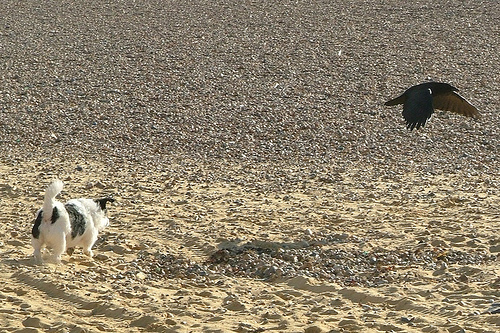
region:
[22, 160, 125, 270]
a white and black dog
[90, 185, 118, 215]
ear of dog is black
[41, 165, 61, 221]
tail of dog is white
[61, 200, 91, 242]
a brown spot on body of dog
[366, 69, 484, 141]
a bird flying in the air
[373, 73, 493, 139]
bird is black and brown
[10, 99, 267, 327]
dog stand in the sand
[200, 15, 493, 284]
bird flying on a field of sand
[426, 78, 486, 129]
wing of bird is brown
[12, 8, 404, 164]
field filled with gravel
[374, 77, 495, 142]
the bird is black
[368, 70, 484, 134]
the bird is flying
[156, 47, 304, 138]
the gravel is gray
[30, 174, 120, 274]
the dog is walking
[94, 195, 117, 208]
the ear is black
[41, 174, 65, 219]
the tail is white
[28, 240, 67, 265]
the dog has back legs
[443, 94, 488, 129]
the bird has a wing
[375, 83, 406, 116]
the bird has a tail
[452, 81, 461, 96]
the bird has a beek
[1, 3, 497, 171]
THE PEBBLES ARE ON THE GROUND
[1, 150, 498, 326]
THE GROUND IS VERY SANDY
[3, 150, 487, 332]
THE SAND HAS MANY TRACKS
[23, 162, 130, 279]
THE DOG IS CHASING THE BIRD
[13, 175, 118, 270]
THE DOG IS BLACK AND WHITE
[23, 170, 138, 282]
THIS IS A DOG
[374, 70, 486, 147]
THIS IS A BIRD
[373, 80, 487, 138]
THE BIRD IS BLACK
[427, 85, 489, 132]
THE UNDERSIDE OF THE BIRD'S WING IS BROWN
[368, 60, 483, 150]
THE BIRD IS FLYING AWAY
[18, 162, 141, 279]
dog on the sand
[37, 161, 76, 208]
tail of the dog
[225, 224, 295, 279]
rocks on the ground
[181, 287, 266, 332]
sand on the ground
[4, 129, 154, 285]
black and white dog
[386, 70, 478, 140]
bird in the air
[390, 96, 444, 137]
wing of the bird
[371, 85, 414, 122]
tail of the bird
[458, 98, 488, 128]
left wing of the bird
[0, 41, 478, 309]
a bird and a dog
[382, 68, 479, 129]
The flying bird above the sand area.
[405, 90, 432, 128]
The left wing of the bird.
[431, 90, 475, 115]
The right wing of the bird.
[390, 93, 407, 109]
The tail of the bird.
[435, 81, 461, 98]
The head of the bird.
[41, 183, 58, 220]
The tail of the dog.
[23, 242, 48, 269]
The left back leg of the dog.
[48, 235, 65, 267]
The right back leg of the dog.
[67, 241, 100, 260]
The front legs of the dog.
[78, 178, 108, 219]
The ear and head of the dog.